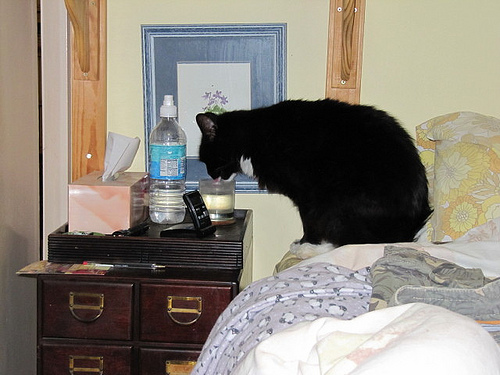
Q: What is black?
A: Cat.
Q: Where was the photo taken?
A: In a room.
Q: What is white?
A: Wall.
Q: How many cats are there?
A: One.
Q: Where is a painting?
A: On the wall.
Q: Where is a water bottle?
A: On a dresser.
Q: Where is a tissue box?
A: On dresser.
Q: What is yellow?
A: Pillow.